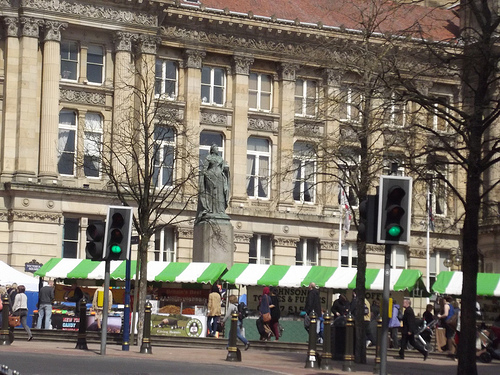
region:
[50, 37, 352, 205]
Building with lots of windows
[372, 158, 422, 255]
traffic light is green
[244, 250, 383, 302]
Green and white roof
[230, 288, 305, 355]
People walking down side walk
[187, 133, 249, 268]
Statue made of concrete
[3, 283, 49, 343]
Woman in white shirt and pants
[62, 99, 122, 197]
Window has white curtains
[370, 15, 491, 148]
Tree with no leaves on it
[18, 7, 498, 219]
Large building with lots of windows.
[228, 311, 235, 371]
Poles in front of business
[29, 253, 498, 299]
green and white awning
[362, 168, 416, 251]
black traffic lights with white frame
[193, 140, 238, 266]
tall statue in background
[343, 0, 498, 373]
tree with no leaves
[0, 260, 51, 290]
white awning in background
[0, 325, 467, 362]
steps in front of flea market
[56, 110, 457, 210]
white curtains inside windows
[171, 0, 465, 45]
red roof on tan-colored building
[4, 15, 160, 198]
ornate columns on either side of windows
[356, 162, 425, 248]
A traffic light is visible.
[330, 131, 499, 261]
A traffic light is visible.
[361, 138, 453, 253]
A traffic light is visible.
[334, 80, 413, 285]
A traffic light is visible.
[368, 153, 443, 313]
A traffic light is visible.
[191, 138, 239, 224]
Lady statue by building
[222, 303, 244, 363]
Black metal poles with gold trim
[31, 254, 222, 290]
Awning is green and white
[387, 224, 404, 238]
Light is green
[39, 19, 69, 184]
Ornate column on building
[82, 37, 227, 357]
Tree is leafless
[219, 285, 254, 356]
Woman wearing black backpack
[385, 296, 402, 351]
Woman wearing purple coat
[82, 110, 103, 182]
White curtain behind window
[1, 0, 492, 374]
Building is large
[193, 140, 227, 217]
this is a statue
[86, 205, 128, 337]
this is a traffic light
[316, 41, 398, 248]
this is a tree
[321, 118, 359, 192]
the leaves are dry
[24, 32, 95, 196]
this is a building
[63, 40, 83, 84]
this is the window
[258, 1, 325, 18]
this is the roof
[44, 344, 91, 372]
this is the road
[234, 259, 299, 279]
this is a tent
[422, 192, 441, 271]
this is a flag